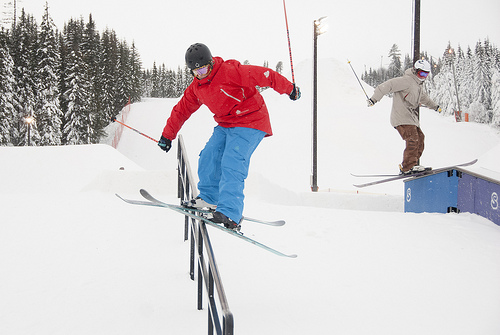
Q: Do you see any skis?
A: Yes, there are skis.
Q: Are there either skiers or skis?
A: Yes, there are skis.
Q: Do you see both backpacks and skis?
A: No, there are skis but no backpacks.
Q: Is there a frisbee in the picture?
A: No, there are no frisbees.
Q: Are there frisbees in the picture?
A: No, there are no frisbees.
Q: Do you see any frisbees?
A: No, there are no frisbees.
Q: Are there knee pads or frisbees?
A: No, there are no frisbees or knee pads.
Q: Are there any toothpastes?
A: No, there are no toothpastes.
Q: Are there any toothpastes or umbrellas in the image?
A: No, there are no toothpastes or umbrellas.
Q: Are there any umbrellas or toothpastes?
A: No, there are no toothpastes or umbrellas.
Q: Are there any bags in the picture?
A: No, there are no bags.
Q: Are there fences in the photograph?
A: No, there are no fences.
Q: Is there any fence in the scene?
A: No, there are no fences.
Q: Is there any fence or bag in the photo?
A: No, there are no fences or bags.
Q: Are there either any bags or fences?
A: No, there are no fences or bags.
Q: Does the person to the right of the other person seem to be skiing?
A: Yes, the person is skiing.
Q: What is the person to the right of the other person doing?
A: The person is skiing.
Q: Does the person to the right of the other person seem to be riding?
A: No, the person is skiing.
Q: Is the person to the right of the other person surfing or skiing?
A: The person is skiing.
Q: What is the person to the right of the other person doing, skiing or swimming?
A: The person is skiing.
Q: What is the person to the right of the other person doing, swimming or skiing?
A: The person is skiing.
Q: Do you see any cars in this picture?
A: No, there are no cars.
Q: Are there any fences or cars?
A: No, there are no cars or fences.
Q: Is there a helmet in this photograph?
A: Yes, there is a helmet.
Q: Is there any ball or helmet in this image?
A: Yes, there is a helmet.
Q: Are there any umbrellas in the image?
A: No, there are no umbrellas.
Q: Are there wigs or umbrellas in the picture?
A: No, there are no umbrellas or wigs.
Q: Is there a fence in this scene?
A: No, there are no fences.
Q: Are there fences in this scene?
A: No, there are no fences.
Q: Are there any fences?
A: No, there are no fences.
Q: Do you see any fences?
A: No, there are no fences.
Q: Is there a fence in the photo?
A: No, there are no fences.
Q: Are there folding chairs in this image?
A: No, there are no folding chairs.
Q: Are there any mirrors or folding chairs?
A: No, there are no folding chairs or mirrors.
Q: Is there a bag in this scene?
A: No, there are no bags.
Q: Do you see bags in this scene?
A: No, there are no bags.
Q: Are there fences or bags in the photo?
A: No, there are no bags or fences.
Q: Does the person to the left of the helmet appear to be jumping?
A: Yes, the person is jumping.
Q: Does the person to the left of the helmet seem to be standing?
A: No, the person is jumping.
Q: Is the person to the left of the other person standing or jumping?
A: The person is jumping.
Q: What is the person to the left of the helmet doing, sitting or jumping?
A: The person is jumping.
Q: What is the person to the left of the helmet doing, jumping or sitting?
A: The person is jumping.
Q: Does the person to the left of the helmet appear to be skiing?
A: Yes, the person is skiing.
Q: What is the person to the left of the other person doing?
A: The person is skiing.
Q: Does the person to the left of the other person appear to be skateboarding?
A: No, the person is skiing.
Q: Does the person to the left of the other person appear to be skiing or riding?
A: The person is skiing.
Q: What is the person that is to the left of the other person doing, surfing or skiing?
A: The person is skiing.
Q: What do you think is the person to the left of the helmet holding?
A: The person is holding the pole.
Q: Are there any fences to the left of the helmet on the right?
A: No, there is a person to the left of the helmet.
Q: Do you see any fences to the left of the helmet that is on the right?
A: No, there is a person to the left of the helmet.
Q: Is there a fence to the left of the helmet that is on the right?
A: No, there is a person to the left of the helmet.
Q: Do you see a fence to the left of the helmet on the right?
A: No, there is a person to the left of the helmet.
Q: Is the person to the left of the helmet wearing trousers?
A: Yes, the person is wearing trousers.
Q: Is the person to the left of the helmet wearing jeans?
A: No, the person is wearing trousers.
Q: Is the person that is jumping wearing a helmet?
A: Yes, the person is wearing a helmet.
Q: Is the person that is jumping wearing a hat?
A: No, the person is wearing a helmet.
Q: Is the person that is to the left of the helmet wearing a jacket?
A: Yes, the person is wearing a jacket.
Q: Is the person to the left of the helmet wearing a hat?
A: No, the person is wearing a jacket.